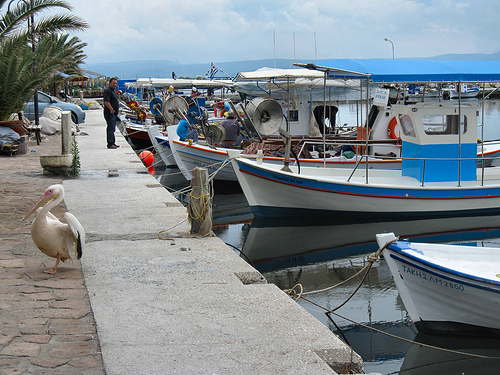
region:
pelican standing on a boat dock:
[15, 166, 282, 311]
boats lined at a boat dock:
[122, 57, 497, 310]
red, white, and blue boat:
[232, 83, 498, 224]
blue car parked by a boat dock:
[10, 71, 107, 134]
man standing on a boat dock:
[94, 41, 180, 191]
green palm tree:
[4, 0, 100, 168]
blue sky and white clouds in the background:
[81, 4, 480, 74]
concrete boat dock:
[96, 92, 280, 372]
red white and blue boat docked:
[322, 221, 497, 336]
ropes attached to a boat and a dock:
[252, 221, 403, 339]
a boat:
[254, 60, 384, 271]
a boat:
[266, 94, 323, 226]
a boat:
[264, 13, 356, 143]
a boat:
[265, 148, 377, 194]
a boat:
[258, 172, 332, 212]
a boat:
[364, 102, 421, 174]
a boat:
[207, 105, 374, 230]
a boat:
[250, 125, 420, 305]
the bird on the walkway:
[21, 184, 83, 265]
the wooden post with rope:
[188, 162, 214, 235]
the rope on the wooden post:
[193, 184, 210, 221]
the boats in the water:
[127, 64, 499, 314]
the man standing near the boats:
[104, 77, 124, 149]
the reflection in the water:
[241, 211, 499, 259]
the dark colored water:
[271, 233, 378, 310]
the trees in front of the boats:
[4, 1, 84, 158]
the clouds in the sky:
[96, 2, 497, 49]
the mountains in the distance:
[88, 50, 493, 85]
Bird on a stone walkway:
[18, 180, 89, 281]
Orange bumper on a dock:
[139, 150, 156, 174]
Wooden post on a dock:
[186, 167, 217, 239]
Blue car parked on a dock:
[26, 87, 91, 129]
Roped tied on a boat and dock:
[283, 246, 378, 302]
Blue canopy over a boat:
[302, 51, 497, 86]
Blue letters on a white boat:
[391, 260, 476, 299]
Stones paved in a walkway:
[3, 277, 95, 372]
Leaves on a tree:
[1, 5, 88, 110]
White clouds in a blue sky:
[112, 3, 471, 51]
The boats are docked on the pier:
[125, 74, 480, 293]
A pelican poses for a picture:
[23, 165, 121, 288]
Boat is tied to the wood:
[185, 161, 216, 244]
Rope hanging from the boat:
[287, 244, 381, 364]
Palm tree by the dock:
[0, 1, 105, 128]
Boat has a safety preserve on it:
[367, 109, 405, 158]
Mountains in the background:
[157, 46, 483, 78]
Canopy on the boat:
[240, 47, 418, 104]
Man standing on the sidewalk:
[103, 67, 125, 157]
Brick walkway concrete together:
[10, 266, 70, 368]